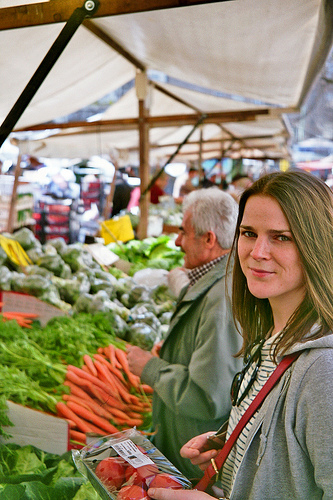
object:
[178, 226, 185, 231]
eye brow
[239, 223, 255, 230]
eye brow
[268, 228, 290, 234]
eye brow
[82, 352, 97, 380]
carrot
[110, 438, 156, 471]
label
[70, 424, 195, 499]
package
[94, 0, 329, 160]
roof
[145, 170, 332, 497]
person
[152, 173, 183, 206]
person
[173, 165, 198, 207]
person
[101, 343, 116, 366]
carrot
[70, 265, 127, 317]
broccoli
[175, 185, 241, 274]
head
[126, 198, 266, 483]
person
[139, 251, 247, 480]
jacket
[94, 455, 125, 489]
tomato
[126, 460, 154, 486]
tomato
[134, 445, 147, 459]
tomato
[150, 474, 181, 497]
tomato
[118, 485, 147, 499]
tomato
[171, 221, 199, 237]
eyebrows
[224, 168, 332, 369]
hair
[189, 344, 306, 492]
strap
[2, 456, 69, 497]
leaves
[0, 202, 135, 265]
signs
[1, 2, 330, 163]
umbrellas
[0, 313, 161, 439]
salad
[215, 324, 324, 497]
shirt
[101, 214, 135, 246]
paper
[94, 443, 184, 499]
tomatoes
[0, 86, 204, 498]
market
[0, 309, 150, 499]
vegetables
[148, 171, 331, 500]
woman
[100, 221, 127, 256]
sticks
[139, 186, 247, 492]
man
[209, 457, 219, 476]
buckle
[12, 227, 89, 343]
produce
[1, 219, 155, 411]
produce